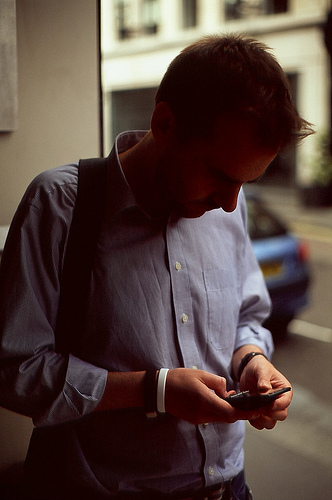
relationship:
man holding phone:
[3, 24, 319, 499] [215, 375, 294, 413]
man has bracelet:
[3, 24, 319, 499] [154, 365, 170, 415]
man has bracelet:
[3, 24, 319, 499] [143, 364, 156, 420]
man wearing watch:
[3, 24, 319, 499] [234, 349, 272, 385]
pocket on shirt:
[198, 263, 240, 357] [42, 190, 256, 386]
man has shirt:
[3, 24, 319, 499] [42, 190, 256, 386]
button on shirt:
[171, 260, 181, 272] [42, 190, 256, 386]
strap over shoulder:
[65, 156, 100, 361] [22, 151, 125, 212]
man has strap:
[3, 24, 319, 499] [65, 156, 100, 361]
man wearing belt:
[3, 24, 319, 499] [124, 481, 247, 499]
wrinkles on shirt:
[111, 257, 171, 364] [42, 190, 256, 386]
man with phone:
[3, 24, 319, 499] [215, 375, 294, 413]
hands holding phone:
[176, 351, 294, 429] [215, 375, 294, 413]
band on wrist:
[154, 365, 170, 415] [127, 361, 193, 420]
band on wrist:
[143, 364, 156, 420] [127, 361, 193, 420]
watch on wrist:
[234, 349, 272, 385] [224, 333, 279, 388]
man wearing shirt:
[3, 24, 319, 499] [42, 190, 256, 386]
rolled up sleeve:
[45, 347, 105, 429] [1, 159, 99, 434]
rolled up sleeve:
[231, 311, 279, 354] [231, 214, 289, 369]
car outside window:
[239, 200, 312, 337] [85, 2, 330, 328]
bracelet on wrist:
[154, 365, 170, 415] [127, 361, 193, 420]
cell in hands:
[215, 375, 294, 413] [164, 365, 260, 428]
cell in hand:
[215, 375, 294, 413] [231, 340, 303, 424]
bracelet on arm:
[143, 364, 156, 420] [18, 347, 212, 421]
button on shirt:
[168, 258, 191, 281] [42, 190, 256, 386]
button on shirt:
[174, 302, 195, 325] [42, 190, 256, 386]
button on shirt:
[184, 354, 203, 373] [42, 190, 256, 386]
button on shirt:
[198, 416, 215, 434] [42, 190, 256, 386]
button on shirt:
[203, 464, 219, 482] [42, 190, 256, 386]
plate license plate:
[258, 258, 284, 279] [255, 260, 285, 283]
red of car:
[297, 239, 308, 264] [239, 200, 312, 337]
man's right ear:
[3, 24, 319, 499] [152, 105, 179, 146]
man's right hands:
[3, 24, 319, 499] [164, 365, 260, 428]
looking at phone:
[198, 149, 273, 204] [215, 375, 294, 413]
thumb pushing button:
[205, 363, 237, 401] [221, 388, 251, 401]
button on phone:
[221, 388, 251, 401] [215, 375, 294, 413]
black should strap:
[78, 161, 96, 211] [65, 156, 100, 361]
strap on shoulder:
[65, 156, 100, 361] [22, 151, 125, 212]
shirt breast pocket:
[42, 190, 256, 386] [198, 263, 240, 357]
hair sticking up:
[163, 36, 298, 131] [223, 28, 277, 67]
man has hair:
[3, 24, 319, 499] [163, 36, 298, 131]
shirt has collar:
[42, 190, 256, 386] [100, 124, 176, 226]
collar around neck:
[100, 124, 176, 226] [122, 129, 168, 198]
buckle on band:
[240, 346, 261, 366] [234, 349, 272, 385]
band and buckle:
[234, 349, 272, 385] [240, 346, 261, 366]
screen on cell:
[245, 385, 284, 402] [215, 375, 294, 413]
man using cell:
[3, 24, 319, 499] [215, 375, 294, 413]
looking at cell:
[198, 149, 273, 204] [215, 375, 294, 413]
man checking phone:
[3, 24, 319, 499] [215, 375, 294, 413]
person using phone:
[3, 24, 319, 499] [215, 375, 294, 413]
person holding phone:
[3, 24, 319, 499] [215, 375, 294, 413]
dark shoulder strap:
[78, 161, 96, 211] [65, 156, 100, 361]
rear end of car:
[239, 200, 312, 337] [238, 192, 312, 337]